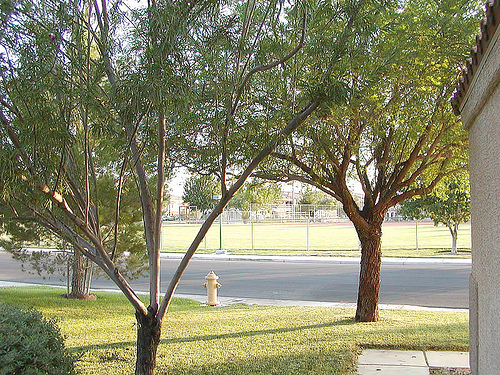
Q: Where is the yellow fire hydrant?
A: Near the sidewalk.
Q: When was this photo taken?
A: During the daytime.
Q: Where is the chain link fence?
A: Across the street.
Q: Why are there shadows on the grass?
A: The sun is shining.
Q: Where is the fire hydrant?
A: Next to the grass.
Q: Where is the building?
A: On the right side.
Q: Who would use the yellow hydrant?
A: Firefighters.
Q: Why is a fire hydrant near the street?
A: For emergency access to water.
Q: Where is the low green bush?
A: In the left corner.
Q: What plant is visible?
A: Tree.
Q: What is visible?
A: Tree.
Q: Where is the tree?
A: In grass.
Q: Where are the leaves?
A: On tree.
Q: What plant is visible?
A: Tree.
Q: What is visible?
A: Tree.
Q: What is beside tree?
A: Another tree.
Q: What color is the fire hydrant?
A: Yellow.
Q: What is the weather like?
A: Sunny.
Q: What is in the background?
A: A park.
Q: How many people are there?
A: Zero.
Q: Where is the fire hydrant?
A: In the grass near the sidewalk.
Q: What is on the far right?
A: The side of a house.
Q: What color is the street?
A: Black.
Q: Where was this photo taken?
A: In a lawn.